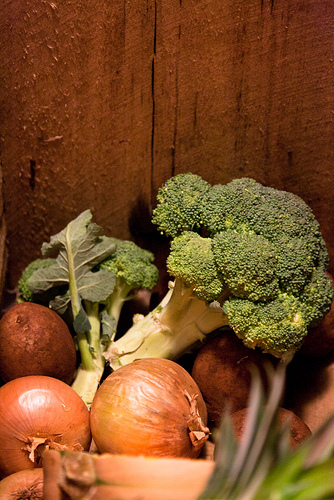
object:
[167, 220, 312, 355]
piece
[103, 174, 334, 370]
broccoli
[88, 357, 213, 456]
onion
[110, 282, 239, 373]
stalk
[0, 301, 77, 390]
potato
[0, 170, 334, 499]
vegetables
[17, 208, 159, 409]
vegetable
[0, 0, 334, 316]
box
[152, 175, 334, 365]
head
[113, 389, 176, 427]
skin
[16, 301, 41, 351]
skin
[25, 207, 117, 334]
leaf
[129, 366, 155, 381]
water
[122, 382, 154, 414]
reflection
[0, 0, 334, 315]
plant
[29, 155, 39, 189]
oval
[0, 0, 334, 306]
plank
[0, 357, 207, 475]
onions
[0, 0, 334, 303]
wall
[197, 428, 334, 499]
leaves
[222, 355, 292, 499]
scallion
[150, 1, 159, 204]
crack